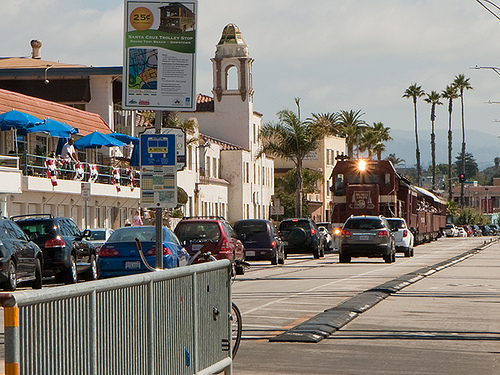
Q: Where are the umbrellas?
A: The balcony.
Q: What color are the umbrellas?
A: Blue.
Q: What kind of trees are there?
A: Palm.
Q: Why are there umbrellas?
A: Shade.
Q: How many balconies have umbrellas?
A: One.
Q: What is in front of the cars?
A: Train.